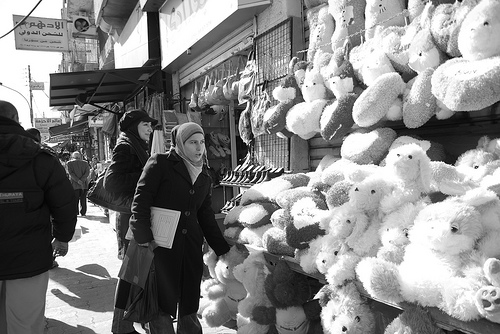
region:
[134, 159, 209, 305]
the coat is black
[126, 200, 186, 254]
the boook is in womans hand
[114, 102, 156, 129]
the hat is black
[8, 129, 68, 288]
the jacket is black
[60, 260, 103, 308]
shadows are on the ground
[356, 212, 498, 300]
the tedy bear is white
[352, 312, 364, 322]
the eyes are black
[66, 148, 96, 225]
the man has hands behind the back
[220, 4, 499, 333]
rows of stuffed animals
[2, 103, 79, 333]
man wearing black coat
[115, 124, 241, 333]
woman touching stuffed animal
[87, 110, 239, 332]
two women standing together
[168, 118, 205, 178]
head scarf of woman touching the stuffed animal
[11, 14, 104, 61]
sign attached to the building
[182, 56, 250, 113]
bags hanging from the eave of a building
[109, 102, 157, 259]
woman wearing black hat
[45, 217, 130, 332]
shadows on the sidewalk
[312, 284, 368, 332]
teddy bear on the ground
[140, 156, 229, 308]
the jacket is black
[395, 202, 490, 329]
the teddy bear is white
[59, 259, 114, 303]
shadow is on ground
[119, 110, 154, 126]
the hat is black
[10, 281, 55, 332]
the pants are white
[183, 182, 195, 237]
the buttons are black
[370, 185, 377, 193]
the eyes are black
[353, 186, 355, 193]
the nose is black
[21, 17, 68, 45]
arabic writng is on the sign